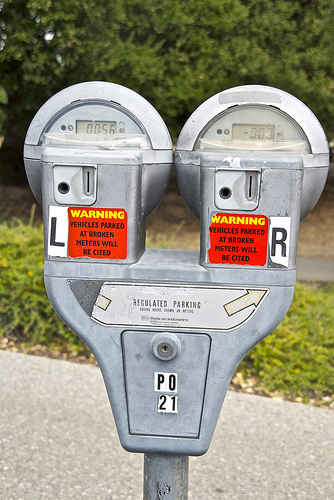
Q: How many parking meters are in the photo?
A: Two.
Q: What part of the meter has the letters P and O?
A: The coin box.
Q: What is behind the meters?
A: Short bushes and trees.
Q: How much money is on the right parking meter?
A: 0.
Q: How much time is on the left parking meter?
A: 56 minutes.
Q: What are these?
A: Parking meters.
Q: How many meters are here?
A: 2.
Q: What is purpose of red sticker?
A: Warning.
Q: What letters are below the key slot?
A: Po.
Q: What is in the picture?
A: Parking meters.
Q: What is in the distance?
A: Trees.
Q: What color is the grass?
A: Green.